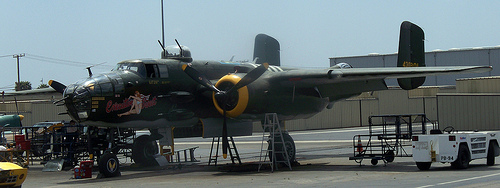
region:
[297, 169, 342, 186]
a ground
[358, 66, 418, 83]
wing of the plane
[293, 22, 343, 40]
the sky is clear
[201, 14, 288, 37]
a clear sky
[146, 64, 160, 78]
window on the plane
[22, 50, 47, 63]
the electrical lines in the sky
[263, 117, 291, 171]
a ladder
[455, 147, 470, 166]
front wheel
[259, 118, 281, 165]
a white ladder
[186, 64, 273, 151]
a propellr on the plane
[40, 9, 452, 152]
This is an airplane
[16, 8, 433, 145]
this is an airplane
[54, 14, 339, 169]
the airple is yellow and black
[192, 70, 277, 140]
the planes engine is yellow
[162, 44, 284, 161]
this is a propeller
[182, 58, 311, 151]
the propeller has three blades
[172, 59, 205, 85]
the propeller tips are yellow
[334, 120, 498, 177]
this is a cargo carrier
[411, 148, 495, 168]
the cargo carrier is white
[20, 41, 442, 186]
this is at an airport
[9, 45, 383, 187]
this is on a runway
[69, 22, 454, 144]
plane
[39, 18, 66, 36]
white clouds in blue sky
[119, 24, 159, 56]
white clouds in blue sky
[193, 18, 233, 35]
white clouds in blue sky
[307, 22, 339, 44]
white clouds in blue sky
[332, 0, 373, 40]
white clouds in blue sky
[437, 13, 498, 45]
white clouds in blue sky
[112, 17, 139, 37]
white clouds in blue sky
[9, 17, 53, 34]
white clouds in blue sky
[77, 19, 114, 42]
white clouds in blue sky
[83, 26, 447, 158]
a large black old plane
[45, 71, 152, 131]
the nose of a plane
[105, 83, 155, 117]
the logo of a plane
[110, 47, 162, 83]
the window of a plane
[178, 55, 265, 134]
the propeller of a plane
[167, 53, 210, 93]
the blade of a plane propeller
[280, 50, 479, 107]
the wing of a plane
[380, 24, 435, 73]
the tail of a plane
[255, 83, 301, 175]
a tall and grey ladder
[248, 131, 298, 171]
the wheel of a plane